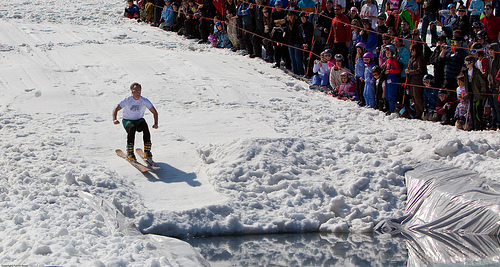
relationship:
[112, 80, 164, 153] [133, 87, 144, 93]
man on goggles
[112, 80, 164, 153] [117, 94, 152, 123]
man wearing shirt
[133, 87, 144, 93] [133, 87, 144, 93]
goggles on goggles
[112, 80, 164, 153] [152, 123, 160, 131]
man has hands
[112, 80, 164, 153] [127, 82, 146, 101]
man has head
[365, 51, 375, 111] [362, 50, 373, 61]
person wearing helmet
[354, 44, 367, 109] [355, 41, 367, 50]
person wearing helmet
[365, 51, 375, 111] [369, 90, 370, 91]
person wearing blue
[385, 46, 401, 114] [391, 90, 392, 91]
person wearing blue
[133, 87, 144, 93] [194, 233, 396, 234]
goggles at edge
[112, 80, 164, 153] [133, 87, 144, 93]
man wearing goggles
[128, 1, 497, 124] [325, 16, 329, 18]
crowd behind rope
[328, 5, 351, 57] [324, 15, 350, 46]
person wearing shirt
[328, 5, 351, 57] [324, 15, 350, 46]
man wearing jacket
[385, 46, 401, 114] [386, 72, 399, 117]
person wearing pants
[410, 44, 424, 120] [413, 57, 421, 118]
person wearing clothes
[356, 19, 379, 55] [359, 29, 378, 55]
person wearing jacket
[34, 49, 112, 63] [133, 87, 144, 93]
lines in goggles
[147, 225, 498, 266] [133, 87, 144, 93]
hole in goggles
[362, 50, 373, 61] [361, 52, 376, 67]
helmet on head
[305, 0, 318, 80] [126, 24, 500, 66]
lines on side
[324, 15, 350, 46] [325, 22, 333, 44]
sweater has long sleeves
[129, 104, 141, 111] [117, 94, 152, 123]
logo on tee shirt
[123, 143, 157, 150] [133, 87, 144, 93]
lines on goggles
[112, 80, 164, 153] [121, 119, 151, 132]
man wearing shorts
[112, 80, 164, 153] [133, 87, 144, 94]
man wearing goggles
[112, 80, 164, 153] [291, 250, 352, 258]
skier approaching water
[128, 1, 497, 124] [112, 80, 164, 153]
audience watches skier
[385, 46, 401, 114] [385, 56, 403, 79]
child wearing shirt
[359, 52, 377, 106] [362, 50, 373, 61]
child wearing helmet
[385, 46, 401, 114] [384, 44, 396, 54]
man has helmet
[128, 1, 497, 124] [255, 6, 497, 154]
crowd of people